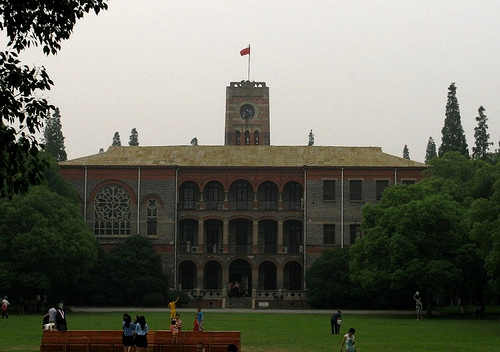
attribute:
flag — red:
[239, 45, 253, 80]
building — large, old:
[55, 81, 428, 308]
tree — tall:
[442, 81, 469, 157]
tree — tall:
[39, 100, 64, 160]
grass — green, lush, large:
[0, 312, 498, 352]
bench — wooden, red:
[37, 330, 243, 352]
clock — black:
[241, 101, 257, 121]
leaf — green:
[44, 44, 52, 60]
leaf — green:
[15, 43, 24, 54]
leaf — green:
[93, 1, 101, 14]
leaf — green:
[54, 40, 62, 54]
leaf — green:
[40, 71, 50, 79]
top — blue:
[135, 323, 149, 334]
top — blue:
[122, 321, 134, 335]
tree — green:
[344, 179, 470, 317]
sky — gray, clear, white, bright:
[0, 0, 499, 162]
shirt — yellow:
[168, 301, 176, 309]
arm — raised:
[174, 297, 181, 305]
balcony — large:
[179, 181, 302, 211]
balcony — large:
[176, 216, 304, 255]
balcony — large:
[180, 258, 301, 298]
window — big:
[87, 180, 134, 236]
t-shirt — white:
[0, 300, 9, 308]